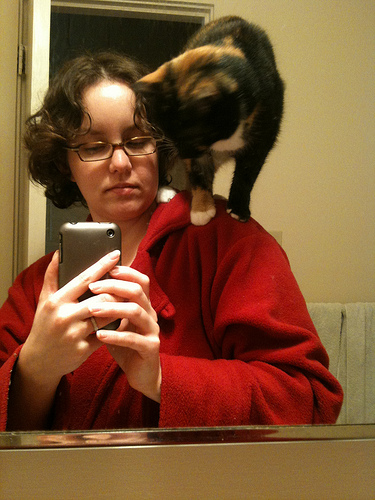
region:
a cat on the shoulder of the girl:
[148, 15, 281, 221]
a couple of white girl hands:
[21, 253, 174, 389]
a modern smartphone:
[48, 220, 126, 313]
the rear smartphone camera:
[98, 225, 124, 249]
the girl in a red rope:
[135, 215, 336, 418]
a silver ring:
[86, 315, 101, 334]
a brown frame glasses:
[69, 133, 157, 161]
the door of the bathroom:
[21, 2, 214, 64]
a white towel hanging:
[314, 294, 370, 422]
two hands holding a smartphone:
[50, 219, 178, 395]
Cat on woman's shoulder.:
[134, 15, 288, 227]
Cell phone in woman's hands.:
[29, 218, 162, 396]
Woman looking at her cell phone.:
[0, 44, 339, 430]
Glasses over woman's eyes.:
[64, 132, 160, 162]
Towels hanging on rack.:
[304, 295, 372, 425]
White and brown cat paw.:
[183, 201, 220, 226]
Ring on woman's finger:
[88, 313, 103, 336]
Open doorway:
[41, 7, 211, 57]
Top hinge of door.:
[16, 40, 27, 78]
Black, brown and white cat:
[133, 15, 285, 227]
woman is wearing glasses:
[59, 124, 182, 180]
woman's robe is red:
[9, 193, 371, 447]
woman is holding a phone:
[47, 209, 138, 288]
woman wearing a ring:
[74, 314, 119, 344]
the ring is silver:
[81, 309, 115, 345]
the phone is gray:
[51, 200, 143, 348]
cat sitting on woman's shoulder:
[133, 0, 329, 271]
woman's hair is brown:
[19, 80, 212, 258]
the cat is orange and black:
[128, 2, 338, 236]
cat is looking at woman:
[136, 41, 349, 244]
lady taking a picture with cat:
[23, 17, 278, 395]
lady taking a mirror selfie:
[16, 28, 286, 399]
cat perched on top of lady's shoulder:
[149, 18, 292, 240]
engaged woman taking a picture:
[19, 212, 164, 407]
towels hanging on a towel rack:
[277, 280, 373, 412]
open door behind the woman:
[18, 4, 213, 254]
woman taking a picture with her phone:
[20, 43, 266, 346]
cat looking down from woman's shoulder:
[137, 36, 270, 273]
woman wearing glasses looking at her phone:
[35, 79, 155, 284]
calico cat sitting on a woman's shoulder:
[122, 10, 297, 299]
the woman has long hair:
[23, 55, 177, 224]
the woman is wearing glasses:
[65, 137, 157, 159]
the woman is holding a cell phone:
[54, 221, 122, 354]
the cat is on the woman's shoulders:
[146, 12, 286, 226]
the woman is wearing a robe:
[1, 188, 339, 432]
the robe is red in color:
[4, 199, 340, 431]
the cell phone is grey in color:
[60, 219, 121, 334]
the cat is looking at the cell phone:
[139, 15, 282, 231]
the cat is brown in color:
[140, 20, 285, 223]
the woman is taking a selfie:
[0, 49, 336, 435]